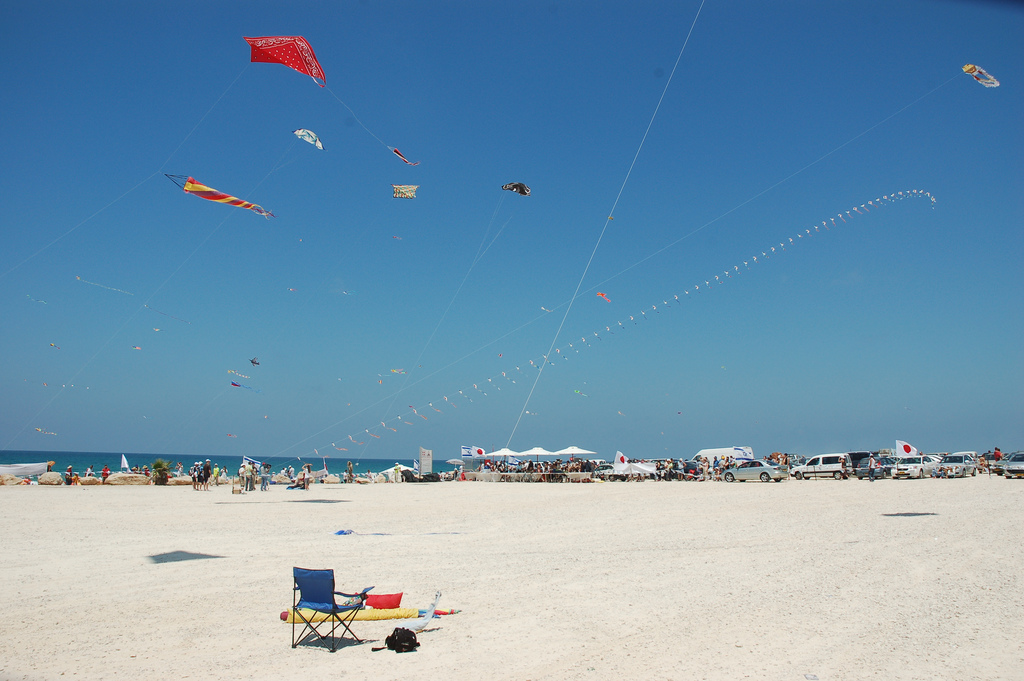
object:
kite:
[165, 173, 275, 221]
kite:
[291, 128, 327, 152]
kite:
[501, 182, 531, 198]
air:
[0, 0, 1022, 457]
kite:
[389, 184, 421, 200]